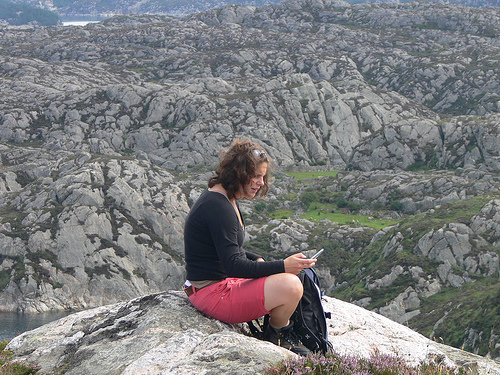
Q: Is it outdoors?
A: Yes, it is outdoors.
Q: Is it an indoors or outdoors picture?
A: It is outdoors.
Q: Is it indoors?
A: No, it is outdoors.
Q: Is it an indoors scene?
A: No, it is outdoors.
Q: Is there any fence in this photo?
A: No, there are no fences.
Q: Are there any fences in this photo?
A: No, there are no fences.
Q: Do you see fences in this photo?
A: No, there are no fences.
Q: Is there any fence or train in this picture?
A: No, there are no fences or trains.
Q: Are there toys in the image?
A: No, there are no toys.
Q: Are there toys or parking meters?
A: No, there are no toys or parking meters.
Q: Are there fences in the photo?
A: No, there are no fences.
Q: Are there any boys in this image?
A: No, there are no boys.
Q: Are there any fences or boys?
A: No, there are no boys or fences.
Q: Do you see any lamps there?
A: No, there are no lamps.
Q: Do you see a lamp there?
A: No, there are no lamps.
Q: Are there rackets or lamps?
A: No, there are no lamps or rackets.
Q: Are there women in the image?
A: Yes, there is a woman.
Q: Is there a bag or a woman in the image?
A: Yes, there is a woman.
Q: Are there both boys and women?
A: No, there is a woman but no boys.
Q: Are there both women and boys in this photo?
A: No, there is a woman but no boys.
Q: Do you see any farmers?
A: No, there are no farmers.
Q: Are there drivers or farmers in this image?
A: No, there are no farmers or drivers.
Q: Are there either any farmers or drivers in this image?
A: No, there are no farmers or drivers.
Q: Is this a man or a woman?
A: This is a woman.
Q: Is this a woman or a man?
A: This is a woman.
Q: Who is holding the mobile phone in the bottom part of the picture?
A: The woman is holding the cell phone.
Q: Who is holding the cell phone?
A: The woman is holding the cell phone.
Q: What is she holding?
A: The woman is holding the cell phone.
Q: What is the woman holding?
A: The woman is holding the cell phone.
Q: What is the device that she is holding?
A: The device is a cell phone.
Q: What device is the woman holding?
A: The woman is holding the cellphone.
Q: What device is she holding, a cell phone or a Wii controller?
A: The woman is holding a cell phone.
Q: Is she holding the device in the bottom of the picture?
A: Yes, the woman is holding the cell phone.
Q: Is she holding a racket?
A: No, the woman is holding the cell phone.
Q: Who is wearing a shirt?
A: The woman is wearing a shirt.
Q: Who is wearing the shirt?
A: The woman is wearing a shirt.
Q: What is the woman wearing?
A: The woman is wearing a shirt.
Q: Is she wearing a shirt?
A: Yes, the woman is wearing a shirt.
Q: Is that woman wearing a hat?
A: No, the woman is wearing a shirt.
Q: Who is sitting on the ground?
A: The woman is sitting on the ground.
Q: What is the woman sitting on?
A: The woman is sitting on the ground.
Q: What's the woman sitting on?
A: The woman is sitting on the ground.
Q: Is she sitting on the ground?
A: Yes, the woman is sitting on the ground.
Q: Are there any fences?
A: No, there are no fences.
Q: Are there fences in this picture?
A: No, there are no fences.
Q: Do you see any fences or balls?
A: No, there are no fences or balls.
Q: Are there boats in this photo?
A: No, there are no boats.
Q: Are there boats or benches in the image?
A: No, there are no boats or benches.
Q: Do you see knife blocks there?
A: No, there are no knife blocks.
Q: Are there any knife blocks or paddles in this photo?
A: No, there are no knife blocks or paddles.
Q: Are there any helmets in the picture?
A: No, there are no helmets.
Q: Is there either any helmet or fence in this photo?
A: No, there are no helmets or fences.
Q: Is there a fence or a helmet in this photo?
A: No, there are no helmets or fences.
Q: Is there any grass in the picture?
A: Yes, there is grass.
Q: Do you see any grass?
A: Yes, there is grass.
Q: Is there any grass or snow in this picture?
A: Yes, there is grass.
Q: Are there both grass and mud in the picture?
A: No, there is grass but no mud.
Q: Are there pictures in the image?
A: No, there are no pictures.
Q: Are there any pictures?
A: No, there are no pictures.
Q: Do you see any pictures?
A: No, there are no pictures.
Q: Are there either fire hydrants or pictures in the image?
A: No, there are no pictures or fire hydrants.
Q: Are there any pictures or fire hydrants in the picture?
A: No, there are no pictures or fire hydrants.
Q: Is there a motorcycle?
A: No, there are no motorcycles.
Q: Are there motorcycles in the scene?
A: No, there are no motorcycles.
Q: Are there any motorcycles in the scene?
A: No, there are no motorcycles.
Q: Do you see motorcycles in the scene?
A: No, there are no motorcycles.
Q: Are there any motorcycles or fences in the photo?
A: No, there are no motorcycles or fences.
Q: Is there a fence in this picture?
A: No, there are no fences.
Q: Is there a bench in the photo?
A: No, there are no benches.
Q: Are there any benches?
A: No, there are no benches.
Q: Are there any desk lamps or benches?
A: No, there are no benches or desk lamps.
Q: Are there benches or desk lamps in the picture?
A: No, there are no benches or desk lamps.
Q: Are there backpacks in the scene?
A: Yes, there is a backpack.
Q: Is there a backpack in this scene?
A: Yes, there is a backpack.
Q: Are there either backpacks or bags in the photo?
A: Yes, there is a backpack.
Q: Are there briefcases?
A: No, there are no briefcases.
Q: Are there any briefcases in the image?
A: No, there are no briefcases.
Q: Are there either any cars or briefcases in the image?
A: No, there are no briefcases or cars.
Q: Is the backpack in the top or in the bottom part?
A: The backpack is in the bottom of the image.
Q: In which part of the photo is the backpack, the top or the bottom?
A: The backpack is in the bottom of the image.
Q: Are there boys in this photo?
A: No, there are no boys.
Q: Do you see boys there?
A: No, there are no boys.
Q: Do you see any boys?
A: No, there are no boys.